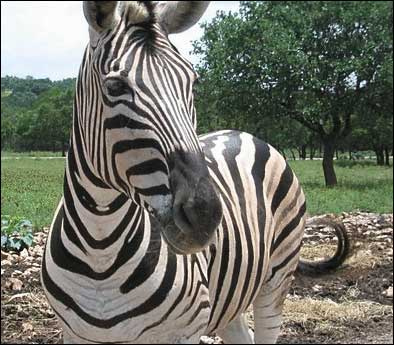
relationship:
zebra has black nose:
[52, 5, 327, 341] [161, 146, 229, 241]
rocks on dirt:
[343, 208, 393, 250] [313, 208, 393, 295]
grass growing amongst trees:
[301, 155, 393, 209] [257, 1, 389, 188]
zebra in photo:
[52, 5, 327, 341] [1, 2, 393, 342]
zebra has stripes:
[52, 5, 327, 341] [36, 4, 317, 344]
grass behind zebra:
[301, 155, 393, 209] [52, 5, 327, 341]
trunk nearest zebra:
[316, 107, 353, 188] [52, 5, 327, 341]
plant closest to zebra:
[257, 1, 389, 188] [52, 5, 327, 341]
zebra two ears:
[52, 5, 327, 341] [77, 0, 215, 36]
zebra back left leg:
[52, 5, 327, 341] [249, 285, 289, 344]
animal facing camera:
[36, 4, 317, 344] [1, 2, 393, 342]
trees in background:
[257, 1, 389, 188] [204, 64, 388, 131]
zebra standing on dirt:
[52, 5, 327, 341] [313, 208, 393, 295]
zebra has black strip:
[52, 5, 327, 341] [76, 57, 106, 160]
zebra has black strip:
[52, 5, 327, 341] [40, 279, 192, 337]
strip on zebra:
[42, 209, 95, 284] [52, 5, 327, 341]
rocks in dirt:
[3, 227, 44, 295] [1, 228, 46, 338]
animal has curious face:
[36, 4, 317, 344] [98, 24, 229, 265]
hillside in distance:
[2, 73, 76, 153] [29, 25, 323, 166]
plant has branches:
[257, 1, 389, 188] [254, 17, 360, 102]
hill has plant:
[8, 64, 275, 122] [2, 73, 76, 153]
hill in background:
[8, 64, 275, 122] [26, 27, 381, 213]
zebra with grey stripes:
[52, 5, 327, 341] [263, 152, 277, 218]